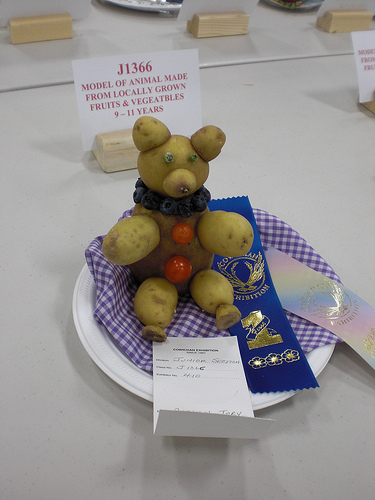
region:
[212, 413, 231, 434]
edge of a paper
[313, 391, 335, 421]
part fo a top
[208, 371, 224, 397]
part f a line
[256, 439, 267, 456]
edge f a shade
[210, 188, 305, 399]
the ribbon on the plate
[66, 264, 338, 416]
the plate is white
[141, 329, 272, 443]
the paper on the plate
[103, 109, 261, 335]
the bear on the plate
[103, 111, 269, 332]
the bear is made of potato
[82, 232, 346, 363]
the napkin under the bear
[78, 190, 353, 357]
the napkin is checkered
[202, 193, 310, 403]
the ribbon is blue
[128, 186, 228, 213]
berries on the bear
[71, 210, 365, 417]
this is a plate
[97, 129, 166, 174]
this is a block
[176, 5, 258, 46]
this is a block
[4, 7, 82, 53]
this is a block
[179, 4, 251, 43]
this is a block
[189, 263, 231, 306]
this is a pototo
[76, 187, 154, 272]
this is a pototo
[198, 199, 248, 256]
this is a pototo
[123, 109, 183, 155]
this is a pototo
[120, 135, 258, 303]
food on a plate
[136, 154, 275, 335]
a food model on a plate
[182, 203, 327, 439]
a first place ribbon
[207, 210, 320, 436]
a blue prize ribbon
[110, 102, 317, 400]
fruits and vegetables on a plate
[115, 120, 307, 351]
fruit and vegetable model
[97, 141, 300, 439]
a plate with purple cloth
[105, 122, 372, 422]
a bear made of fruit and vegetable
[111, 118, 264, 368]
a model of a bear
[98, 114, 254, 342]
a potato teddy bear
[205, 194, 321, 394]
a blue and gold ribbon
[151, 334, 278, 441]
a white sheet of paper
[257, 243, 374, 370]
a white and gold ribbon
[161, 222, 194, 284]
two red tomatoes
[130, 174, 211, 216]
a round blueberry collar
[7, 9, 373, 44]
three rectangular wooden blocks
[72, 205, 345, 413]
a round white plate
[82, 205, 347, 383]
white and purple cloth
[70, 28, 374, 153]
two white printed cards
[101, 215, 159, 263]
arm made of potato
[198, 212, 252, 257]
arm made of potato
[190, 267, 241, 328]
leg made of potato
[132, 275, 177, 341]
leg made of potato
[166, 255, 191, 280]
tomato stuck to potato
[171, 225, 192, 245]
tomato stuck to potato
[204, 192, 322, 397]
blue ribbon sits on plate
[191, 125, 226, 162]
ear is made of potato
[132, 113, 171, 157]
ear is made of potato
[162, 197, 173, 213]
a blue berry on the potato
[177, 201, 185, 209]
a blue berry on the potato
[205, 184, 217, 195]
a blue berry on the potato